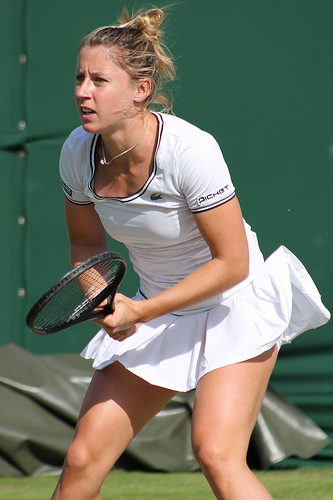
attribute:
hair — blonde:
[78, 5, 175, 107]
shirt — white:
[57, 113, 264, 306]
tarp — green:
[2, 344, 328, 477]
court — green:
[2, 461, 331, 497]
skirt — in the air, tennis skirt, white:
[75, 244, 331, 393]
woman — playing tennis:
[26, 9, 331, 498]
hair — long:
[83, 8, 177, 112]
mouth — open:
[78, 103, 100, 119]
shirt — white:
[55, 108, 268, 319]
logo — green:
[146, 190, 167, 205]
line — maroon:
[85, 106, 166, 209]